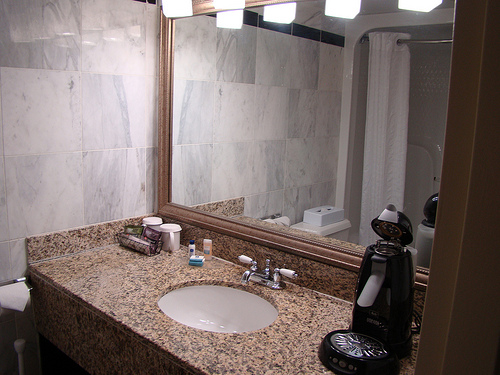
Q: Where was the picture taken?
A: Bathroom.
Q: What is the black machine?
A: Coffee maker.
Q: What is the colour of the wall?
A: White.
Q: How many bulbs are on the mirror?
A: 4.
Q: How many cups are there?
A: 2.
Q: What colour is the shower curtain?
A: White.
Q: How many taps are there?
A: Two.